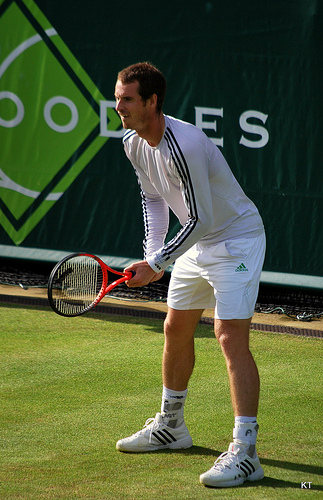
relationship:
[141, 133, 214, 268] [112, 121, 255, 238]
stripes on shirt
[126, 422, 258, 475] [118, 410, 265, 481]
stripes on shoes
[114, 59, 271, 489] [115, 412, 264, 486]
player wearing tennis shoes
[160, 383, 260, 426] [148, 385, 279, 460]
splints on socks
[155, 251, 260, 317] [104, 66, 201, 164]
tennis shorts on player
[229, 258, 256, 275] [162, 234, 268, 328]
logo on shorts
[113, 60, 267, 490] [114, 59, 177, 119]
man has hair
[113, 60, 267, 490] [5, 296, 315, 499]
man playing on court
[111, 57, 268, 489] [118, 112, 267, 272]
man wearing white shirt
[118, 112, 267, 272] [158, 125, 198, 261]
white shirt with black stripes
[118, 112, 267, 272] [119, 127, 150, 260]
white shirt with black stripes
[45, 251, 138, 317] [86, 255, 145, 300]
racket with handle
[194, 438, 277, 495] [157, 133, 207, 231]
shoe with stripes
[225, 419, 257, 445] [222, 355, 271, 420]
sock on calf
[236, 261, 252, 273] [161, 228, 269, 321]
logo on shorts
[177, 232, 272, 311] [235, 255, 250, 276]
shorts with symbol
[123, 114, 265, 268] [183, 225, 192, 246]
shirt has stripes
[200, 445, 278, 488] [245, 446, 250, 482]
tennis shoes has stripes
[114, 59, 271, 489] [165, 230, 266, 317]
player has shorts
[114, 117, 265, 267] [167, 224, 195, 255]
shirt has stripes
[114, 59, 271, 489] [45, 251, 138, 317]
player has racket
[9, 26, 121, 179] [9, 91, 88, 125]
sign has sponsorship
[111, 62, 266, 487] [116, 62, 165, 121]
tennis player has hair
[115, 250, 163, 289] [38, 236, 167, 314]
hands have racket